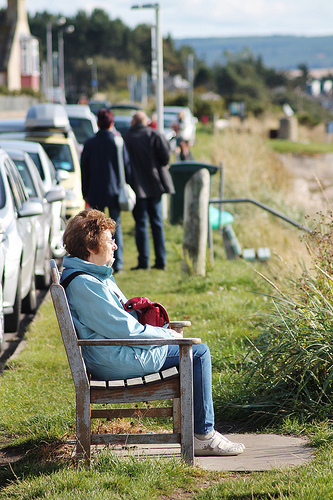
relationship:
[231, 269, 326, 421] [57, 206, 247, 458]
bush near old lady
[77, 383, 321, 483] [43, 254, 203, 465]
cement under bench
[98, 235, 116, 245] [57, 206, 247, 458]
glasses on old lady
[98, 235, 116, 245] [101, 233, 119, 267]
glasses on face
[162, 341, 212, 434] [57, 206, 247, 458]
jeans on old lady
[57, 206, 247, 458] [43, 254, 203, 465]
old lady sits on bench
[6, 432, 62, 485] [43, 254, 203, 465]
shadow of bench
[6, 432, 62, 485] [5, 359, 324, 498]
shadow on ground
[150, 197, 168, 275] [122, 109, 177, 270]
leg of a person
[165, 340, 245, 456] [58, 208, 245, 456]
leg of a person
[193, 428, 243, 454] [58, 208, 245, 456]
feet of a person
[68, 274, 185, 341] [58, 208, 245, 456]
arm of a person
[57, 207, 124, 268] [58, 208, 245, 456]
head of a person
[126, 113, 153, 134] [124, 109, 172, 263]
head of a person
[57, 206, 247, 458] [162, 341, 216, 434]
old lady has jeans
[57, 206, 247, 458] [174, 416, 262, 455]
old lady has shoes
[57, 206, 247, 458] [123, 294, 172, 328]
old lady holding purse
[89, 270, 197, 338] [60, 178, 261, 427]
bag on woman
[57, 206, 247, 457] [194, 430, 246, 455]
old lady wearing shoes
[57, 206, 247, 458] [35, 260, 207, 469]
old lady sitting on a bench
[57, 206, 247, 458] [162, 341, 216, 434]
old lady wearing jeans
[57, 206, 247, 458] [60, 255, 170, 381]
old lady wearing a coat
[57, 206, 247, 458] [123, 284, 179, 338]
old lady holding purse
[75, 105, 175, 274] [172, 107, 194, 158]
people standing away from lady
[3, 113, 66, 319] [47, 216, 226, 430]
cars behind woman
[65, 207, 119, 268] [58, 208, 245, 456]
head on person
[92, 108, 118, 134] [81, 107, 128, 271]
head on person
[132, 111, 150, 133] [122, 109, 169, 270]
head on person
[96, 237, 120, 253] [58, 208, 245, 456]
nose of person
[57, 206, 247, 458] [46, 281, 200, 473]
old lady sitting on bench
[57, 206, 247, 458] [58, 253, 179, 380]
old lady wearing jacket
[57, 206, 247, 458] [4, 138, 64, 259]
old lady behind cars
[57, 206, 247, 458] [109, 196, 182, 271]
old lady wears jeans